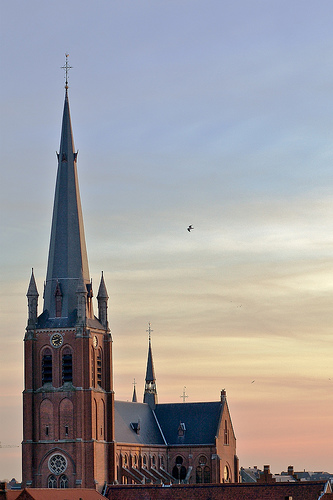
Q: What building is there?
A: Church.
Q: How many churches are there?
A: One.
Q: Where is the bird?
A: Sky.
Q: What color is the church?
A: Brown.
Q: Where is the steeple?
A: Top.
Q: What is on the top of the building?
A: Compass.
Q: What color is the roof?
A: Black.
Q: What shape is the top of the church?
A: Triangle.